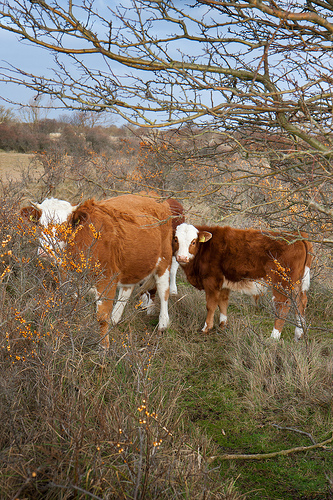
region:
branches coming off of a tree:
[17, 10, 330, 131]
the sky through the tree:
[29, 12, 322, 61]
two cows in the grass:
[29, 195, 323, 353]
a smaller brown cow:
[172, 218, 304, 324]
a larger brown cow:
[23, 178, 182, 329]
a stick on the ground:
[212, 438, 326, 463]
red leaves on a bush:
[8, 219, 93, 353]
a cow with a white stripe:
[174, 223, 203, 261]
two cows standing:
[16, 180, 323, 344]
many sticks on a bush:
[83, 415, 188, 470]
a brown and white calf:
[176, 219, 330, 336]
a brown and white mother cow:
[18, 184, 207, 328]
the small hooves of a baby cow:
[191, 272, 233, 335]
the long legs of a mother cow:
[96, 277, 135, 362]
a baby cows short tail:
[282, 226, 314, 301]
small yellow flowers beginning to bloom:
[97, 389, 192, 491]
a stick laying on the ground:
[212, 422, 331, 474]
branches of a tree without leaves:
[101, 13, 299, 139]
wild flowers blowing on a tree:
[23, 217, 106, 293]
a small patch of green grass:
[205, 381, 242, 449]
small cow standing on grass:
[158, 197, 329, 342]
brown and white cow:
[163, 219, 310, 340]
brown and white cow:
[34, 180, 184, 332]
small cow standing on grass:
[28, 182, 194, 355]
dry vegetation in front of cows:
[18, 362, 224, 483]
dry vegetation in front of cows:
[6, 241, 110, 374]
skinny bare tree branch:
[211, 126, 330, 181]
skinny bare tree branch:
[193, 19, 269, 69]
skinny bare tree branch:
[15, 58, 106, 99]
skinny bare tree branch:
[2, 11, 91, 70]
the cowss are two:
[30, 197, 315, 355]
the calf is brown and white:
[175, 225, 313, 340]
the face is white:
[173, 223, 198, 256]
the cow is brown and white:
[36, 195, 176, 343]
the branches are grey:
[29, 377, 148, 453]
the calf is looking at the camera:
[176, 227, 309, 329]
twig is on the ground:
[256, 439, 309, 470]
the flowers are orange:
[133, 155, 168, 178]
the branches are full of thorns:
[66, 20, 266, 140]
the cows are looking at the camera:
[12, 196, 319, 351]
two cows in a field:
[16, 184, 315, 346]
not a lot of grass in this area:
[159, 362, 331, 498]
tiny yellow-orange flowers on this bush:
[1, 211, 105, 363]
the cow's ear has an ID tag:
[196, 229, 207, 243]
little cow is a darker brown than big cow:
[16, 186, 313, 349]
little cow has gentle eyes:
[171, 233, 199, 247]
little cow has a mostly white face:
[171, 219, 200, 268]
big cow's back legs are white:
[109, 261, 173, 335]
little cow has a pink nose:
[175, 252, 188, 263]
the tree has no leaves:
[1, 1, 330, 151]